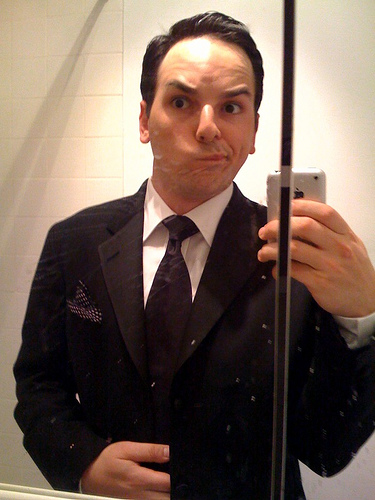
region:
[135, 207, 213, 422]
THE MAN IS WEARING A TIE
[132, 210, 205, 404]
THE TIE IS BLACK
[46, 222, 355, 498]
THE MIRROR IS DIRTY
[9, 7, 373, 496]
THE MAN IS TAKING A MIRROR SELFIE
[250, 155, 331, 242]
THE MAN IS HOLDING A PHONE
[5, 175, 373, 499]
THE MAN IS WEARING A JACKET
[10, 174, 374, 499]
THE MAN'S JACKET IS BLACK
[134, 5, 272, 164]
THE MAN HAS SHORT HAIR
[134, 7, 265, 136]
THE MAN HAS DARK HAIR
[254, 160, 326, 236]
THE MAN'S PHONE IS SILVER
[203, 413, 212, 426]
part of a coat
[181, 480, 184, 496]
part of a button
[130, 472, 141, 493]
part of an hand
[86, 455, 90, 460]
edge of a coat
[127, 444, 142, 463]
part of a finger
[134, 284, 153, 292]
part of a coat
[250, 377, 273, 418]
part of a mirror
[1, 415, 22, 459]
edge of a wall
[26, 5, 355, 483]
man taking mirror selfie with skeptical expression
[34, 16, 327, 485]
Man in mirror wearing a suit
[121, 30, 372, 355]
Man taking selfie with an iphone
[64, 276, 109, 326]
dark polka dot pocket hankerchief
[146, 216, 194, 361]
black necktie against white dress shirt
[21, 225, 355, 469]
surface of mirror is spotted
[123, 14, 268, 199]
man making face with nicely groomed hair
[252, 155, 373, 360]
hand holding a silver phone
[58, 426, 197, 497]
placing hand inside of jacket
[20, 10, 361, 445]
grown man making silly face in a mirror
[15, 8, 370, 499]
man taking a selfie in the mirror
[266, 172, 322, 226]
back view of an iphone in man's hand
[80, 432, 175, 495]
man's hand in his coat jacket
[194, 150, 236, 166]
man's mouth to the side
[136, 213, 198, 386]
black tie on the man's neck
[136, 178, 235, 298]
white collard shirt on the man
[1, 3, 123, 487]
white tile behind the man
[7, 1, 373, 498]
mirror showing a man taking a selfie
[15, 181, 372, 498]
black coat on the man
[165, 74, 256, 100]
man's eyebrows are slanted inward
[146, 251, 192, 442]
Purple tie on man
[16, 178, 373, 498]
Black suit jacket on man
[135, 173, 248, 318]
White collared shirt on man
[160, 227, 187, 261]
Knot of tied tie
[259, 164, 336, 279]
White apple phone in man's hand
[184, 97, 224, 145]
Nose on man's face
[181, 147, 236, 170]
Mouth on man's face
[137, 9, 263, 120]
Black hair on man's head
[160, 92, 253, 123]
Eyes on man's face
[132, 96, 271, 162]
Ears on man's head